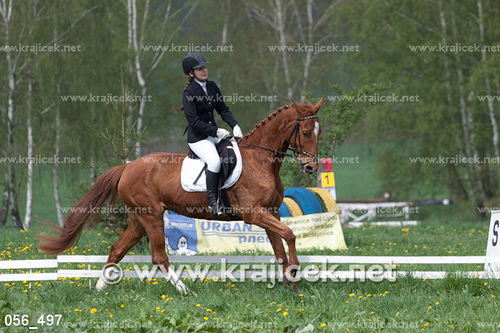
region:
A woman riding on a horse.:
[176, 51, 243, 216]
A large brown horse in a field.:
[37, 97, 324, 296]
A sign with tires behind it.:
[159, 207, 347, 251]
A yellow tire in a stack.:
[309, 186, 342, 215]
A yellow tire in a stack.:
[283, 195, 305, 219]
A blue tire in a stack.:
[281, 182, 322, 215]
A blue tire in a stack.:
[275, 197, 286, 213]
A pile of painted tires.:
[275, 185, 338, 217]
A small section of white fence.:
[0, 255, 498, 290]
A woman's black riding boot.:
[203, 165, 221, 216]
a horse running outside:
[91, 52, 383, 307]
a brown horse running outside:
[36, 54, 447, 255]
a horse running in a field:
[119, 104, 414, 325]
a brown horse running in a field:
[98, 79, 476, 327]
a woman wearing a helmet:
[174, 13, 327, 265]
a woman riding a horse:
[144, 47, 319, 249]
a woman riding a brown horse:
[86, 46, 360, 303]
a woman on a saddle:
[96, 63, 356, 281]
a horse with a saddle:
[109, 74, 429, 291]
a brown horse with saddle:
[107, 54, 336, 271]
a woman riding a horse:
[66, 54, 392, 303]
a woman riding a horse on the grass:
[61, 50, 338, 323]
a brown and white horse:
[66, 81, 358, 328]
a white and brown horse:
[34, 88, 323, 330]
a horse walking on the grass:
[71, 107, 323, 332]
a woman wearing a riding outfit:
[155, 51, 263, 169]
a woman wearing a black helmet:
[172, 49, 230, 99]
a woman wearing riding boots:
[158, 54, 259, 214]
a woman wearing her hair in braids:
[162, 48, 224, 124]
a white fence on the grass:
[1, 233, 491, 330]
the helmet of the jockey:
[183, 55, 205, 70]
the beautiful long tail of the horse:
[36, 163, 118, 251]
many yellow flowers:
[68, 290, 380, 325]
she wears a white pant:
[189, 140, 219, 169]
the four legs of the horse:
[98, 205, 302, 292]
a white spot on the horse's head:
[311, 122, 318, 132]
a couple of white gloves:
[218, 125, 242, 139]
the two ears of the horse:
[293, 95, 324, 111]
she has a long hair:
[180, 75, 190, 110]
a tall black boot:
[204, 168, 224, 214]